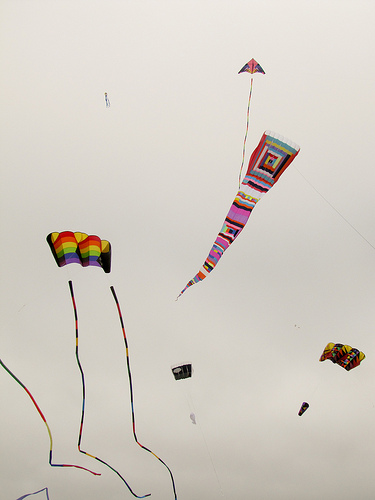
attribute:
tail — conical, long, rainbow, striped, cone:
[183, 194, 260, 307]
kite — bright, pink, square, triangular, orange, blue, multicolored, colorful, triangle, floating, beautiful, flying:
[177, 135, 298, 293]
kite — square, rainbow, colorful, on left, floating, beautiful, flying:
[44, 229, 118, 274]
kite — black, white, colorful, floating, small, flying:
[174, 363, 195, 381]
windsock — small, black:
[299, 397, 313, 422]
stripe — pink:
[225, 210, 251, 228]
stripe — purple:
[234, 198, 253, 221]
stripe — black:
[202, 261, 221, 275]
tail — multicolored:
[109, 287, 181, 499]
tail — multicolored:
[67, 279, 154, 499]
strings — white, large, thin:
[238, 70, 255, 193]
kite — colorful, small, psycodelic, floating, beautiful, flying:
[322, 341, 372, 374]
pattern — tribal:
[167, 198, 251, 296]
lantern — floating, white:
[234, 57, 263, 175]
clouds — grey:
[6, 1, 349, 498]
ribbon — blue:
[0, 345, 99, 483]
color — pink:
[220, 194, 252, 234]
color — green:
[207, 229, 248, 257]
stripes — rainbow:
[43, 238, 113, 271]